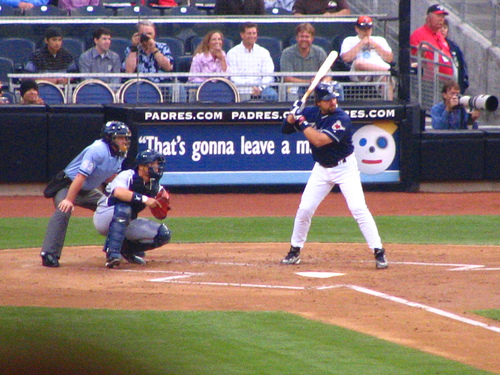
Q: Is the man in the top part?
A: Yes, the man is in the top of the image.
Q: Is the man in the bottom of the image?
A: No, the man is in the top of the image.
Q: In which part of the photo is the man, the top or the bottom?
A: The man is in the top of the image.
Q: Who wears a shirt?
A: The man wears a shirt.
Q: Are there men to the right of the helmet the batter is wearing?
A: Yes, there is a man to the right of the helmet.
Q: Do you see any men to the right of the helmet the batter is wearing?
A: Yes, there is a man to the right of the helmet.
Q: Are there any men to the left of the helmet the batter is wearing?
A: No, the man is to the right of the helmet.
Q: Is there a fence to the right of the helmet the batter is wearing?
A: No, there is a man to the right of the helmet.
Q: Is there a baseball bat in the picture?
A: Yes, there is a baseball bat.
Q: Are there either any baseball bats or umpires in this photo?
A: Yes, there is a baseball bat.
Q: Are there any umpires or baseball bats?
A: Yes, there is a baseball bat.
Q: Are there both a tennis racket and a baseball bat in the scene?
A: No, there is a baseball bat but no rackets.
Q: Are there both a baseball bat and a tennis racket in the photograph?
A: No, there is a baseball bat but no rackets.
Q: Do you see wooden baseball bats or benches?
A: Yes, there is a wood baseball bat.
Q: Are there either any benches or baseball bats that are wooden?
A: Yes, the baseball bat is wooden.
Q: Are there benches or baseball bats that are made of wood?
A: Yes, the baseball bat is made of wood.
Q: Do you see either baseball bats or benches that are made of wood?
A: Yes, the baseball bat is made of wood.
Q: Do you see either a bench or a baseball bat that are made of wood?
A: Yes, the baseball bat is made of wood.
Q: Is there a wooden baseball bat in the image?
A: Yes, there is a wood baseball bat.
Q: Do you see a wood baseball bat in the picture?
A: Yes, there is a wood baseball bat.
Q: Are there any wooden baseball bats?
A: Yes, there is a wood baseball bat.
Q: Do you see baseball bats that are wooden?
A: Yes, there is a baseball bat that is wooden.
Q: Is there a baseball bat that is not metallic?
A: Yes, there is a wooden baseball bat.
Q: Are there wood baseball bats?
A: Yes, there is a baseball bat that is made of wood.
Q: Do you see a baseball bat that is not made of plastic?
A: Yes, there is a baseball bat that is made of wood.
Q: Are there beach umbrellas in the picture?
A: No, there are no beach umbrellas.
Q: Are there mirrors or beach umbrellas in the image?
A: No, there are no beach umbrellas or mirrors.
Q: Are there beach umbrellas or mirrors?
A: No, there are no beach umbrellas or mirrors.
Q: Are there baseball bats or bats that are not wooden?
A: No, there is a baseball bat but it is wooden.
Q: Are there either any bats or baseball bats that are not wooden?
A: No, there is a baseball bat but it is wooden.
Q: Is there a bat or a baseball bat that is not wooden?
A: No, there is a baseball bat but it is wooden.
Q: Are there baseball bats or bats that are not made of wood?
A: No, there is a baseball bat but it is made of wood.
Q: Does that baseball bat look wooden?
A: Yes, the baseball bat is wooden.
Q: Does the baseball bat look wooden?
A: Yes, the baseball bat is wooden.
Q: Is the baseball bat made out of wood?
A: Yes, the baseball bat is made of wood.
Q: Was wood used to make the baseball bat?
A: Yes, the baseball bat is made of wood.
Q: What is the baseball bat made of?
A: The baseball bat is made of wood.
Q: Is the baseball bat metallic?
A: No, the baseball bat is wooden.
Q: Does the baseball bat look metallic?
A: No, the baseball bat is wooden.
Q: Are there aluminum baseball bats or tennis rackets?
A: No, there is a baseball bat but it is wooden.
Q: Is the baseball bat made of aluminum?
A: No, the baseball bat is made of wood.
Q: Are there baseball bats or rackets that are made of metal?
A: No, there is a baseball bat but it is made of wood.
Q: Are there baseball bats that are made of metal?
A: No, there is a baseball bat but it is made of wood.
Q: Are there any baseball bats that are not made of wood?
A: No, there is a baseball bat but it is made of wood.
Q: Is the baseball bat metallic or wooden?
A: The baseball bat is wooden.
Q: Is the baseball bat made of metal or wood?
A: The baseball bat is made of wood.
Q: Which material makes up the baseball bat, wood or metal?
A: The baseball bat is made of wood.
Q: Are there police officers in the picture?
A: No, there are no police officers.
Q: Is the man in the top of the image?
A: Yes, the man is in the top of the image.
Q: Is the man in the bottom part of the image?
A: No, the man is in the top of the image.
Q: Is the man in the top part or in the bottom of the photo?
A: The man is in the top of the image.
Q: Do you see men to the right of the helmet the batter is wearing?
A: Yes, there is a man to the right of the helmet.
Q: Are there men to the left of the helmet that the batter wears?
A: No, the man is to the right of the helmet.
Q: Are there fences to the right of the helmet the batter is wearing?
A: No, there is a man to the right of the helmet.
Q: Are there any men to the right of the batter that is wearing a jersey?
A: Yes, there is a man to the right of the batter.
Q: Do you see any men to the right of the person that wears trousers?
A: Yes, there is a man to the right of the batter.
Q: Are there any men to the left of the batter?
A: No, the man is to the right of the batter.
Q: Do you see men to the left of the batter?
A: No, the man is to the right of the batter.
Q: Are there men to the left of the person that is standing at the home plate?
A: No, the man is to the right of the batter.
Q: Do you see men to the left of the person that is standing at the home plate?
A: No, the man is to the right of the batter.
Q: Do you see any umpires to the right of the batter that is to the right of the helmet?
A: No, there is a man to the right of the batter.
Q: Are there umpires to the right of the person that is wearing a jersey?
A: No, there is a man to the right of the batter.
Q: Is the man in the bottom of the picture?
A: No, the man is in the top of the image.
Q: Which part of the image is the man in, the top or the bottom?
A: The man is in the top of the image.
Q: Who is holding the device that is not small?
A: The man is holding the camera.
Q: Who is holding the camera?
A: The man is holding the camera.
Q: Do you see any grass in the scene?
A: Yes, there is grass.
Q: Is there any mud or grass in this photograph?
A: Yes, there is grass.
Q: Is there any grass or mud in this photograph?
A: Yes, there is grass.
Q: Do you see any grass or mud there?
A: Yes, there is grass.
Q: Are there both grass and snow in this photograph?
A: No, there is grass but no snow.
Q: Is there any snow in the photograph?
A: No, there is no snow.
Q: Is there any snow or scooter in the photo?
A: No, there are no snow or scooters.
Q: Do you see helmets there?
A: Yes, there is a helmet.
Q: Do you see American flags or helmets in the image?
A: Yes, there is a helmet.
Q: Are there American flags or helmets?
A: Yes, there is a helmet.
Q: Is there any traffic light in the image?
A: No, there are no traffic lights.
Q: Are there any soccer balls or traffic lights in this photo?
A: No, there are no traffic lights or soccer balls.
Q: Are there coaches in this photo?
A: No, there are no coaches.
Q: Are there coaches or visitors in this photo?
A: No, there are no coaches or visitors.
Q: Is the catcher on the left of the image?
A: Yes, the catcher is on the left of the image.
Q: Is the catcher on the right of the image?
A: No, the catcher is on the left of the image.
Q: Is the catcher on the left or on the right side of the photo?
A: The catcher is on the left of the image.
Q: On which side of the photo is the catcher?
A: The catcher is on the left of the image.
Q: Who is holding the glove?
A: The catcher is holding the glove.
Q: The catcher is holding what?
A: The catcher is holding the glove.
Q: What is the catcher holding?
A: The catcher is holding the glove.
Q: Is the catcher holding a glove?
A: Yes, the catcher is holding a glove.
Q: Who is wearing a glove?
A: The catcher is wearing a glove.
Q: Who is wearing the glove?
A: The catcher is wearing a glove.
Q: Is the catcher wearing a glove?
A: Yes, the catcher is wearing a glove.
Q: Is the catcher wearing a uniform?
A: No, the catcher is wearing a glove.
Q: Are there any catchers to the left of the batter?
A: Yes, there is a catcher to the left of the batter.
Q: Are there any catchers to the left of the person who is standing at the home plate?
A: Yes, there is a catcher to the left of the batter.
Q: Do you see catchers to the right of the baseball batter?
A: No, the catcher is to the left of the batter.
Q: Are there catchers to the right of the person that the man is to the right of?
A: No, the catcher is to the left of the batter.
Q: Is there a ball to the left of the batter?
A: No, there is a catcher to the left of the batter.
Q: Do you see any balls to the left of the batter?
A: No, there is a catcher to the left of the batter.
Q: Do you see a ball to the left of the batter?
A: No, there is a catcher to the left of the batter.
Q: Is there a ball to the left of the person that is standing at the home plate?
A: No, there is a catcher to the left of the batter.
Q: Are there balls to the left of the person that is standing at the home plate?
A: No, there is a catcher to the left of the batter.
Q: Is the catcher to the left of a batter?
A: Yes, the catcher is to the left of a batter.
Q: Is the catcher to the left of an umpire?
A: No, the catcher is to the left of a batter.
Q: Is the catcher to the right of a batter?
A: No, the catcher is to the left of a batter.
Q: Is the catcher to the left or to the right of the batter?
A: The catcher is to the left of the batter.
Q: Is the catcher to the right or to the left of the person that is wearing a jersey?
A: The catcher is to the left of the batter.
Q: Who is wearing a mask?
A: The catcher is wearing a mask.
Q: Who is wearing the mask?
A: The catcher is wearing a mask.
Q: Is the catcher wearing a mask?
A: Yes, the catcher is wearing a mask.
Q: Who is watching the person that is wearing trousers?
A: The catcher is watching the batter.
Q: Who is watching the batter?
A: The catcher is watching the batter.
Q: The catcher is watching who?
A: The catcher is watching the batter.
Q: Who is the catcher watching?
A: The catcher is watching the batter.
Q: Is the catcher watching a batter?
A: Yes, the catcher is watching a batter.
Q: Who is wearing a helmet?
A: The catcher is wearing a helmet.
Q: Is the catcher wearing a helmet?
A: Yes, the catcher is wearing a helmet.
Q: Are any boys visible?
A: No, there are no boys.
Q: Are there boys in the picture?
A: No, there are no boys.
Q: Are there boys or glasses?
A: No, there are no boys or glasses.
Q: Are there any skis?
A: No, there are no skis.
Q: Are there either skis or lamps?
A: No, there are no skis or lamps.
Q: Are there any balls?
A: No, there are no balls.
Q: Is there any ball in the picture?
A: No, there are no balls.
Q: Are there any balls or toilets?
A: No, there are no balls or toilets.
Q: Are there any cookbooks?
A: No, there are no cookbooks.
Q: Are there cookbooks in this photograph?
A: No, there are no cookbooks.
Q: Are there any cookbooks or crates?
A: No, there are no cookbooks or crates.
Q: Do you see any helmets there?
A: Yes, there is a helmet.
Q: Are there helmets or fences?
A: Yes, there is a helmet.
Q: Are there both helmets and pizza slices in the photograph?
A: No, there is a helmet but no pizza slices.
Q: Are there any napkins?
A: No, there are no napkins.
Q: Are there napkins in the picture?
A: No, there are no napkins.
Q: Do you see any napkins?
A: No, there are no napkins.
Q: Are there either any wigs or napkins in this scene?
A: No, there are no napkins or wigs.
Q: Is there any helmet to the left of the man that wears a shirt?
A: Yes, there is a helmet to the left of the man.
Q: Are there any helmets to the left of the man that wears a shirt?
A: Yes, there is a helmet to the left of the man.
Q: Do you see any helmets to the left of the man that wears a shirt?
A: Yes, there is a helmet to the left of the man.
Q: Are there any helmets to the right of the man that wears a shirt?
A: No, the helmet is to the left of the man.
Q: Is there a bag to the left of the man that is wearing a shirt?
A: No, there is a helmet to the left of the man.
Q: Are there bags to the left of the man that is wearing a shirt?
A: No, there is a helmet to the left of the man.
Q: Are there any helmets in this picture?
A: Yes, there is a helmet.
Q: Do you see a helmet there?
A: Yes, there is a helmet.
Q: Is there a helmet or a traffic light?
A: Yes, there is a helmet.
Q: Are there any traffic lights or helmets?
A: Yes, there is a helmet.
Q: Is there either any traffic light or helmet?
A: Yes, there is a helmet.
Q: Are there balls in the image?
A: No, there are no balls.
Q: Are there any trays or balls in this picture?
A: No, there are no balls or trays.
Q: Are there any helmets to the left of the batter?
A: Yes, there is a helmet to the left of the batter.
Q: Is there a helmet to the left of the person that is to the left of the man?
A: Yes, there is a helmet to the left of the batter.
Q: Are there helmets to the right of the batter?
A: No, the helmet is to the left of the batter.